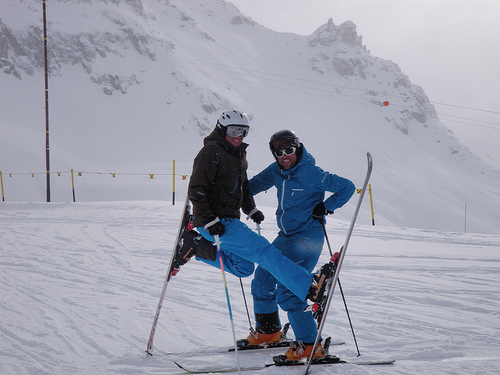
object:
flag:
[57, 172, 62, 177]